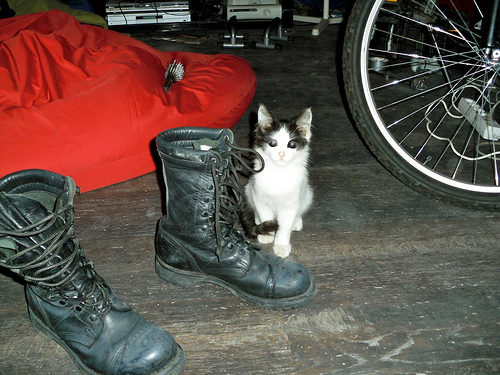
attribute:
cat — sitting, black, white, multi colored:
[238, 102, 314, 259]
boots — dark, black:
[0, 125, 317, 374]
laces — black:
[210, 136, 265, 261]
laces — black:
[0, 186, 111, 321]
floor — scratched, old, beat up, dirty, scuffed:
[1, 26, 498, 375]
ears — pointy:
[258, 102, 313, 133]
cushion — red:
[0, 8, 256, 196]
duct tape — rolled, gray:
[368, 55, 390, 72]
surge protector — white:
[457, 97, 499, 139]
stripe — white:
[361, 0, 499, 195]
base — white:
[293, 0, 343, 35]